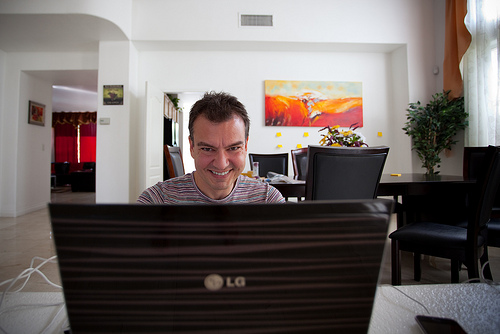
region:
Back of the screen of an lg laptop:
[47, 197, 397, 329]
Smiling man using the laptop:
[140, 76, 300, 206]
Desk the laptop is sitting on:
[1, 280, 496, 330]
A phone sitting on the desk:
[405, 305, 465, 330]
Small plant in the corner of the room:
[400, 80, 465, 175]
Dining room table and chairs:
[162, 141, 499, 282]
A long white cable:
[3, 235, 68, 313]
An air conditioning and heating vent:
[237, 7, 277, 34]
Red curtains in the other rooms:
[56, 122, 96, 162]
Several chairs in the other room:
[52, 156, 97, 188]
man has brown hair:
[179, 66, 259, 192]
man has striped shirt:
[152, 173, 305, 223]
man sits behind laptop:
[125, 105, 298, 220]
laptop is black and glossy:
[40, 187, 381, 332]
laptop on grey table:
[44, 177, 356, 329]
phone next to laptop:
[393, 291, 489, 331]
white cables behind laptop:
[2, 255, 57, 296]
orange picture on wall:
[247, 82, 394, 115]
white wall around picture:
[207, 54, 284, 76]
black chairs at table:
[376, 150, 498, 272]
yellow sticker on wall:
[274, 129, 281, 137]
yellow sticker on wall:
[299, 129, 311, 136]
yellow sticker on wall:
[376, 132, 383, 139]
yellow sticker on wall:
[275, 142, 284, 148]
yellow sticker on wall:
[291, 144, 305, 151]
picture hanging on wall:
[103, 84, 122, 105]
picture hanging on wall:
[27, 96, 48, 130]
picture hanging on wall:
[262, 78, 362, 125]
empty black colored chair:
[304, 144, 384, 199]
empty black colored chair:
[385, 140, 487, 283]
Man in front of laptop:
[135, 90, 287, 202]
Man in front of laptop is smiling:
[130, 92, 287, 202]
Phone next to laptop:
[415, 313, 467, 332]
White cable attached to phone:
[387, 283, 432, 315]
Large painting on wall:
[262, 78, 364, 128]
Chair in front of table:
[389, 139, 499, 284]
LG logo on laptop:
[203, 268, 247, 293]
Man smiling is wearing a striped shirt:
[136, 88, 286, 203]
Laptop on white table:
[47, 200, 391, 332]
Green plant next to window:
[400, 88, 470, 174]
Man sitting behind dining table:
[133, 85, 285, 205]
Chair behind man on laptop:
[303, 138, 388, 198]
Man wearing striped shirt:
[127, 91, 285, 202]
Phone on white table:
[413, 312, 466, 332]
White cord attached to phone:
[386, 279, 430, 313]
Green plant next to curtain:
[400, 90, 470, 173]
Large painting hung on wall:
[260, 78, 362, 127]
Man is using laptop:
[131, 90, 287, 201]